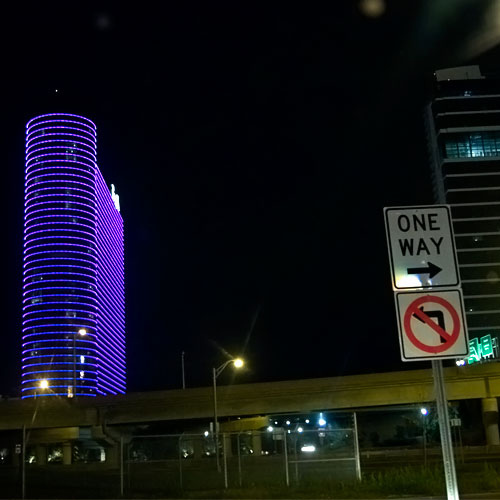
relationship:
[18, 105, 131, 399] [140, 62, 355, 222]
skyscrapers at night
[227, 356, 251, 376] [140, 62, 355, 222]
lamp at night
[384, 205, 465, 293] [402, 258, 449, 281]
one-way sign arrow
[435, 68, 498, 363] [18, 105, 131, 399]
building with purple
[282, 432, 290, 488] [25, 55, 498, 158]
aluminum fence skyline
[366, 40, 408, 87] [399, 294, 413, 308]
black and white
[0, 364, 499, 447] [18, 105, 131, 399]
bridge front skyscrapers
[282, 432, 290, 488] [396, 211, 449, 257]
aluminum pole one-way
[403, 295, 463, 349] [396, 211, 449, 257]
no left one-way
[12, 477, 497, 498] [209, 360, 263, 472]
street lamp post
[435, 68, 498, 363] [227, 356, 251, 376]
building glowing lamp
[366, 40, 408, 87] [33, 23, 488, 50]
black night sky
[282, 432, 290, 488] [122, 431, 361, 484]
aluminum chain fence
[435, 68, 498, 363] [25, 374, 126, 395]
building one story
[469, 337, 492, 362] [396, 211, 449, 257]
green highway one-way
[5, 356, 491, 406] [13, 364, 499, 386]
roadway by bridge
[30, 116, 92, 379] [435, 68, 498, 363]
neon highrise building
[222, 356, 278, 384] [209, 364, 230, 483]
lamp metal pole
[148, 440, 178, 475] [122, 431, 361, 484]
chain link fence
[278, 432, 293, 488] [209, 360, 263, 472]
aluminum fence post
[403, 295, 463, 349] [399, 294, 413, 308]
red black white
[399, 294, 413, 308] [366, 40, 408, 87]
white sign black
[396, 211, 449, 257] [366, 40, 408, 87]
one-way has black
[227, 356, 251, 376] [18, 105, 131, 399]
lamp on skyscrapers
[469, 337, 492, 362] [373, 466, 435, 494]
green patch weeds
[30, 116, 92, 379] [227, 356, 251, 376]
purple building lamp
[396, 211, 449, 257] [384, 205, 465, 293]
one-way says one-way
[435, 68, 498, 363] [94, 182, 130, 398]
building on side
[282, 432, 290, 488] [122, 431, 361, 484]
aluminum tall fence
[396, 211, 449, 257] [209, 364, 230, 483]
one-way on pole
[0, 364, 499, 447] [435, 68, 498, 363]
bridge in front building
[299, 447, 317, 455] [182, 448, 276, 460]
headlights from cars